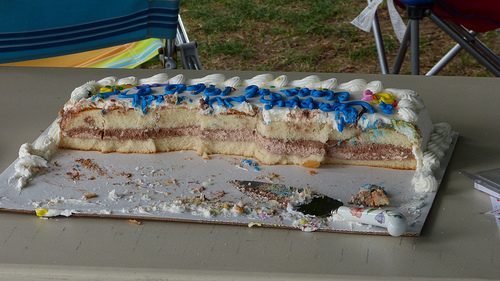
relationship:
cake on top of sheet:
[7, 74, 454, 193] [0, 114, 460, 237]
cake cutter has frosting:
[224, 178, 410, 239] [226, 179, 324, 208]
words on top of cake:
[93, 82, 394, 115] [7, 74, 454, 193]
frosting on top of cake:
[62, 72, 424, 122] [7, 74, 454, 193]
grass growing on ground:
[131, 2, 499, 77] [132, 0, 499, 79]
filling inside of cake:
[65, 123, 417, 161] [7, 74, 454, 193]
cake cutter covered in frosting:
[224, 178, 410, 239] [226, 179, 324, 208]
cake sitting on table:
[7, 74, 454, 193] [0, 64, 500, 280]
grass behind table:
[131, 2, 499, 77] [0, 64, 500, 280]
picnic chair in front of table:
[1, 0, 205, 70] [0, 64, 500, 280]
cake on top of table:
[7, 74, 454, 193] [0, 64, 500, 280]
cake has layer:
[7, 74, 454, 193] [56, 136, 419, 171]